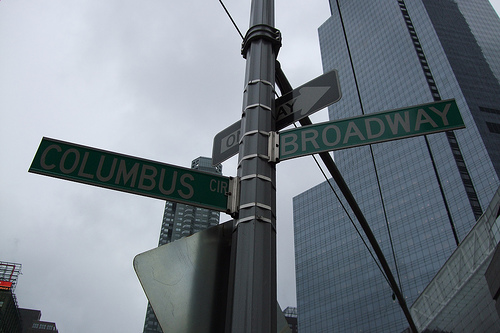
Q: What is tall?
A: Buildings.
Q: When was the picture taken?
A: Daytime.